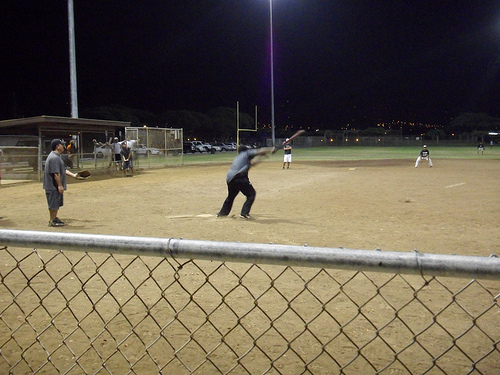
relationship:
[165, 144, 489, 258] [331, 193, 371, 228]
field made of dirt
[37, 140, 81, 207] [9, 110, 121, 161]
players in dugout